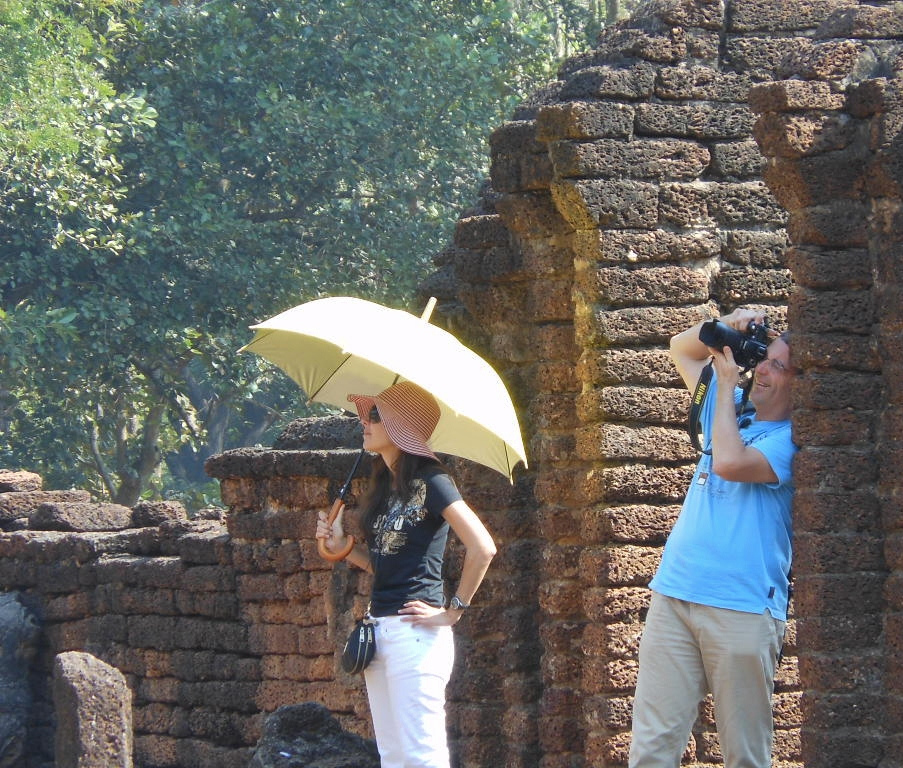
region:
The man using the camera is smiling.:
[648, 300, 800, 754]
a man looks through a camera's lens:
[632, 291, 819, 613]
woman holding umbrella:
[254, 292, 499, 761]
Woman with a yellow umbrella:
[241, 255, 544, 754]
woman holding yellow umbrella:
[230, 294, 531, 766]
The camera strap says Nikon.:
[683, 340, 737, 463]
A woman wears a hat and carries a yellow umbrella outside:
[231, 176, 557, 725]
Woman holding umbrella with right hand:
[223, 272, 546, 722]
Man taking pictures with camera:
[654, 292, 832, 515]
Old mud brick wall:
[10, 452, 274, 715]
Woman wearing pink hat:
[336, 368, 453, 484]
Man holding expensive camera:
[668, 285, 798, 461]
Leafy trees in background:
[11, 150, 199, 480]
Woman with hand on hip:
[305, 377, 504, 638]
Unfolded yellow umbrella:
[236, 265, 535, 489]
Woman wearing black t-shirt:
[290, 345, 528, 679]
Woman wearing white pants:
[305, 392, 492, 766]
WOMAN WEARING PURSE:
[233, 252, 609, 761]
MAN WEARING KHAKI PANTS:
[661, 263, 862, 748]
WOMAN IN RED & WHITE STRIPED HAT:
[220, 304, 579, 733]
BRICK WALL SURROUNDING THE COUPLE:
[28, 420, 304, 627]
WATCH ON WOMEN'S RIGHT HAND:
[397, 586, 538, 662]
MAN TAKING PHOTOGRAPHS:
[637, 154, 889, 516]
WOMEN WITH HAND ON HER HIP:
[308, 488, 581, 663]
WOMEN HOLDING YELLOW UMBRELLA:
[319, 291, 583, 738]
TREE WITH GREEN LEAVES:
[20, 227, 285, 330]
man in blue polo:
[654, 270, 811, 675]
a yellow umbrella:
[212, 217, 700, 576]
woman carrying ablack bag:
[334, 591, 402, 690]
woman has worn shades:
[333, 377, 412, 447]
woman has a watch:
[428, 576, 518, 654]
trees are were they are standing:
[85, 242, 188, 377]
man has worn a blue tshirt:
[681, 496, 750, 594]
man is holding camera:
[676, 288, 811, 453]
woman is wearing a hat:
[351, 369, 487, 467]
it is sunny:
[127, 224, 196, 458]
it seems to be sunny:
[56, 63, 756, 642]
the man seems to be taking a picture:
[602, 303, 822, 657]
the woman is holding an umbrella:
[183, 282, 572, 698]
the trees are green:
[64, 322, 199, 409]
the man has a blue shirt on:
[628, 304, 822, 716]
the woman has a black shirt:
[267, 437, 519, 665]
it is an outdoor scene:
[101, 366, 806, 723]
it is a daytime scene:
[25, 350, 799, 704]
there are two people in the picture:
[199, 343, 811, 708]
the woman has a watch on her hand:
[377, 551, 638, 692]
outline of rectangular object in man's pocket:
[721, 602, 771, 666]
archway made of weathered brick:
[546, 157, 842, 751]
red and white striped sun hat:
[344, 374, 442, 468]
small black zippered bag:
[332, 616, 378, 674]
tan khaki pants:
[624, 579, 789, 760]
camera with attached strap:
[682, 309, 771, 463]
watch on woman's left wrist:
[442, 583, 472, 620]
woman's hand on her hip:
[372, 581, 470, 658]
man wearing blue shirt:
[643, 332, 792, 624]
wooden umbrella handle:
[308, 485, 358, 563]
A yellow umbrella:
[240, 281, 531, 477]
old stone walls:
[18, 461, 272, 697]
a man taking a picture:
[661, 312, 837, 741]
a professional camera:
[676, 321, 767, 438]